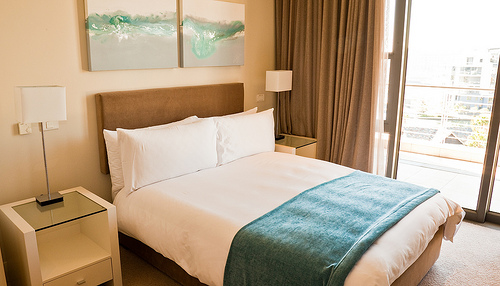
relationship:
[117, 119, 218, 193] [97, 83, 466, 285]
pillow on bed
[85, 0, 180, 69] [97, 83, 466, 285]
painting over bed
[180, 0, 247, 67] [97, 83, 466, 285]
painting over bed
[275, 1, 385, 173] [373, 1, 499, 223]
curtain on window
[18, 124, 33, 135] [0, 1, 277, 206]
light switch on wall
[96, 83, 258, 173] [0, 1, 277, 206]
head board on wall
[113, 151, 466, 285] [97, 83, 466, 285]
linen on bed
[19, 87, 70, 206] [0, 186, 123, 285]
lamp on nightstand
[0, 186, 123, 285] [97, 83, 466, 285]
nightstand next to bed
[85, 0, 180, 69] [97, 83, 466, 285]
painting above bed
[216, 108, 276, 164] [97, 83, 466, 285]
pillow on bed